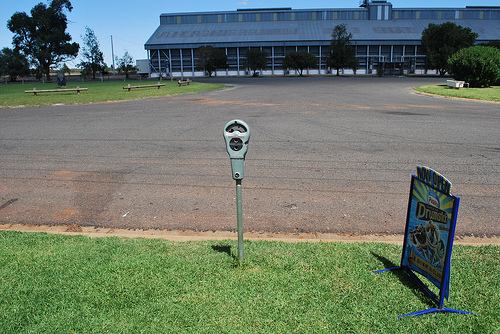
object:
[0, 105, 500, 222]
parking lot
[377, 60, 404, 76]
entrance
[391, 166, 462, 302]
frame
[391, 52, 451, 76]
cones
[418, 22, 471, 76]
large tree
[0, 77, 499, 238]
road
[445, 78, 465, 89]
bench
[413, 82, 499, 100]
grass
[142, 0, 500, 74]
building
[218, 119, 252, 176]
parking meter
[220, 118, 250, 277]
metal pole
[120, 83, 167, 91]
wooden bench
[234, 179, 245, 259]
pole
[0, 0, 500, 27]
sky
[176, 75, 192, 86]
bench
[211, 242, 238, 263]
shadow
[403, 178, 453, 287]
background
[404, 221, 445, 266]
cone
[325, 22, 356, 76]
tree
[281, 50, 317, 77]
tree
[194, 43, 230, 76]
tree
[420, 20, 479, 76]
tree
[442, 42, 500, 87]
bush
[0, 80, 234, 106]
grass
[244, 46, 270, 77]
tree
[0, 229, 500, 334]
grass